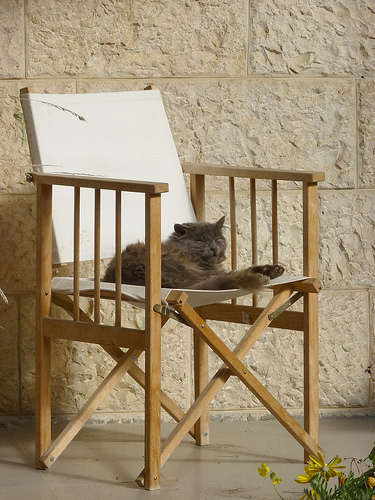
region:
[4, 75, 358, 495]
a wooden chair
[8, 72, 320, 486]
Chair made of cloth and wood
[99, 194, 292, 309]
Sleeping cat on the chair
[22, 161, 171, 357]
wooden chair arm rest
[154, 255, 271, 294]
cat's tail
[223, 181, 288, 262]
three spindles made of wood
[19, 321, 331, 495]
chair's legs are made of wood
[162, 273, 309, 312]
chair sitting made of cloth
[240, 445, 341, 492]
yellow flowers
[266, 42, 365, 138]
wall made of stone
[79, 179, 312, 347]
a lazy cat sitting on a director's chair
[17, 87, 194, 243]
the fabric back of the director's chair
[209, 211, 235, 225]
the pointed tip of the cat's ear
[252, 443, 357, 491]
yellow flowers in front of the chair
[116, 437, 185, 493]
wooden legs in front of the chair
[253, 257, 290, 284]
the paw of the cat on the chair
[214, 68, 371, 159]
the plastered brick wall behind the chair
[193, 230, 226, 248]
the closed eyes of the cat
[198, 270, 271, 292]
the bushy tail on the cat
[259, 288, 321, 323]
the steel hinge on the chair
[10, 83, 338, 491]
Wooden Chair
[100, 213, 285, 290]
Cat asleep in chair.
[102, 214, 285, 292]
Black cat laying down in a chair.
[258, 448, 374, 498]
Yellow flowers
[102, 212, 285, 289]
Cat with eyes closed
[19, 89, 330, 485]
Chair is brown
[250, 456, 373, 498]
Yellow flowers have green leaves.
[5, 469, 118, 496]
Floor is made of cement.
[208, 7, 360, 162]
Tan brick wall.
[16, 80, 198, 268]
Wooden chair has a cream colored cloth on it.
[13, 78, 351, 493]
a cat sitting on a chair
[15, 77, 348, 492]
cat sitting on a chair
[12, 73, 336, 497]
cat sitting on chair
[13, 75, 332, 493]
cat sitting on a chair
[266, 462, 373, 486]
yellow flowers on the ground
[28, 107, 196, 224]
white back of the chair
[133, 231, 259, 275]
gray cat in the chair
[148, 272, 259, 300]
the gray cats tail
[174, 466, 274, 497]
the gray concrete floor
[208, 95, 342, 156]
the textured cement block wall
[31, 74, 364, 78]
line in between the concrete wall blocks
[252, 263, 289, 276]
one of the gray cats feet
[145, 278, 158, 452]
a wooden leg of the chair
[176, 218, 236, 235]
the ears of the gray cat